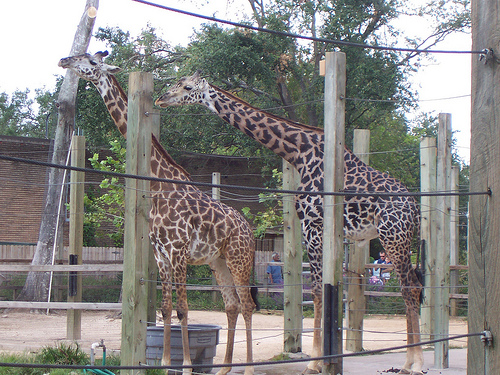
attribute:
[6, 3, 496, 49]
sky — sunny, clear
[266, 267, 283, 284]
shirt — blue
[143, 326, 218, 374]
trash can — large, gray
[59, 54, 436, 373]
giraffes — large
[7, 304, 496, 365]
ground — brown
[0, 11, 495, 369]
zoo pen — wooden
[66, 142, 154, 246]
tree — big, leafy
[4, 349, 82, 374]
grass — green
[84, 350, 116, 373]
garden hose — green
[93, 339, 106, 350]
faucet — silver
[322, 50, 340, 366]
post — large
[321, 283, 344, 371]
bottom — black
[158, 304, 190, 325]
knees — wide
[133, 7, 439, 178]
trees — green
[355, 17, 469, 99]
branch — long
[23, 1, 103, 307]
tree trunk — dead, tall, gray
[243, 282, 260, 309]
tail — tufted, black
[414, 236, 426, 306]
tail — tufted, black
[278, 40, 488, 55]
rods — metal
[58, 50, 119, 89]
giraffe head — raised, spotted